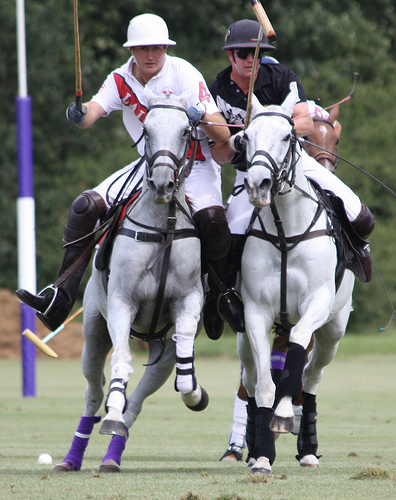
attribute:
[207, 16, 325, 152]
polo player — playing, trying to hit ball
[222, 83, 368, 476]
horse — white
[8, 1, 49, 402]
pole — blue, white, purple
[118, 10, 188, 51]
hat — white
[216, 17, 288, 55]
hat — black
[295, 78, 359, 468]
horse — brown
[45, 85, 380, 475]
horses — being ridden, white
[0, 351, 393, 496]
area — green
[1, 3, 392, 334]
trees — green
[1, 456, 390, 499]
ground — green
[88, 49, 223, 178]
jersey — red, white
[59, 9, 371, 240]
two people — racing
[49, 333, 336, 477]
hooves — here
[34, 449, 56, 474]
ball — white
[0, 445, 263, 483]
shade — here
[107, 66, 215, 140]
cloth — here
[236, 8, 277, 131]
wood — here